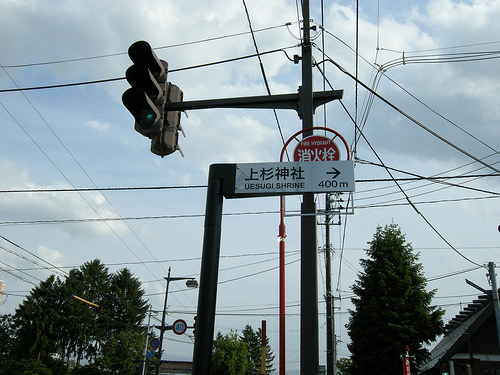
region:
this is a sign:
[219, 148, 366, 199]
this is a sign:
[276, 114, 361, 212]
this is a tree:
[341, 218, 451, 372]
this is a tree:
[228, 310, 281, 374]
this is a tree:
[196, 314, 253, 374]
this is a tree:
[93, 253, 164, 372]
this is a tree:
[57, 242, 112, 370]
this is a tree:
[1, 266, 79, 363]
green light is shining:
[137, 104, 161, 130]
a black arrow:
[324, 166, 340, 178]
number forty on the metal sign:
[171, 318, 188, 335]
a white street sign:
[233, 163, 355, 195]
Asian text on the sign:
[244, 166, 303, 181]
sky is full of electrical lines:
[3, 11, 490, 301]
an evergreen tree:
[345, 220, 441, 359]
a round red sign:
[291, 133, 340, 160]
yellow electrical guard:
[70, 290, 101, 309]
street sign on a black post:
[195, 160, 352, 373]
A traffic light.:
[123, 40, 187, 158]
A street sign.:
[211, 162, 356, 192]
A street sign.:
[278, 127, 360, 159]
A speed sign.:
[153, 318, 191, 333]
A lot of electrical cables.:
[332, 40, 497, 175]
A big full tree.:
[345, 221, 440, 348]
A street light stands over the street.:
[161, 262, 201, 290]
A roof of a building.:
[430, 280, 492, 365]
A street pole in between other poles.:
[292, 200, 319, 370]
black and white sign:
[230, 130, 347, 196]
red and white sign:
[295, 121, 343, 176]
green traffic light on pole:
[110, 53, 170, 150]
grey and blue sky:
[35, 0, 132, 144]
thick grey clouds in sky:
[42, 8, 147, 195]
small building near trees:
[408, 304, 493, 368]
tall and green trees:
[347, 234, 422, 343]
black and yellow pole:
[257, 320, 273, 372]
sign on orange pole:
[272, 124, 341, 371]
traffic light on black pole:
[170, 85, 328, 365]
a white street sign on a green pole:
[213, 155, 363, 196]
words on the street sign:
[241, 168, 352, 190]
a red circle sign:
[285, 126, 339, 169]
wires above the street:
[24, 25, 474, 280]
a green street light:
[127, 37, 187, 164]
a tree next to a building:
[349, 223, 416, 372]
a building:
[421, 290, 495, 354]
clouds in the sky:
[26, 103, 143, 211]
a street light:
[156, 265, 193, 368]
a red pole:
[273, 217, 288, 373]